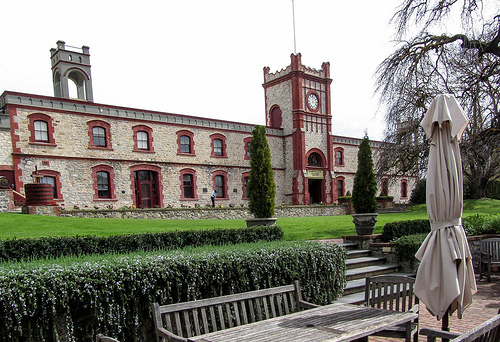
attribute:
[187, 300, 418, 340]
table — wooden, rectangular, wood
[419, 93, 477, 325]
umbrella — Closed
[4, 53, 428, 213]
building — Stone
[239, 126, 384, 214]
trees — small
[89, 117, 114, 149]
window — Closed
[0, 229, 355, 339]
hedge — green, long, short, linear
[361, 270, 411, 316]
chair — wooden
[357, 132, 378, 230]
hedge — Green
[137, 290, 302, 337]
bench — wooden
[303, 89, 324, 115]
clock — Round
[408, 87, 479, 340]
umbrella — unopened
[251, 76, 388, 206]
building — brick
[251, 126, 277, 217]
bush. — tall, green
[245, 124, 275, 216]
tree — potted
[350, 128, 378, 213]
tree — potted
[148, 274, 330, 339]
bench — Brown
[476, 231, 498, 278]
bench — Brown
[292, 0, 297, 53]
pole — on top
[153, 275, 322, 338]
bench — long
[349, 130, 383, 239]
tree — small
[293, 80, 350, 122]
clock — Round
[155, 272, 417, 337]
table — wooden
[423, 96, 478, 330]
umbrella — Stored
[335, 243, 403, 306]
stairs — Short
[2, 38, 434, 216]
building — Tall, tan, brick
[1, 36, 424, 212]
estate — Elegant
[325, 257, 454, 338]
chair — wooden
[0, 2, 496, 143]
sky — HAS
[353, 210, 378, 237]
vase — Stone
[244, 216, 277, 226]
vase — Stone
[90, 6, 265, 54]
clouds — IN THE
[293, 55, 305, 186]
trim — red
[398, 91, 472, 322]
umbrella — tan, closed